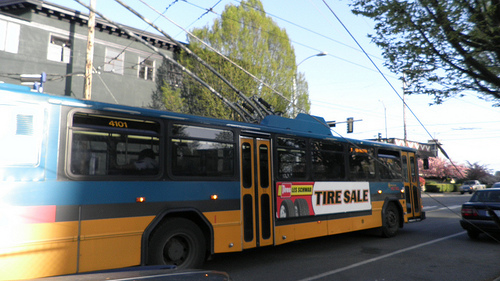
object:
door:
[240, 135, 276, 248]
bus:
[2, 83, 432, 270]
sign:
[273, 180, 368, 217]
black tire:
[153, 217, 210, 267]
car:
[455, 187, 500, 239]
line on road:
[411, 207, 463, 253]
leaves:
[383, 19, 442, 62]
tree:
[374, 0, 498, 106]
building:
[0, 5, 290, 113]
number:
[105, 120, 131, 128]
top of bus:
[1, 96, 421, 153]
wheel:
[378, 202, 401, 234]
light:
[208, 193, 214, 200]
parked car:
[454, 180, 483, 194]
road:
[236, 206, 499, 280]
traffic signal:
[324, 116, 355, 132]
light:
[312, 50, 327, 59]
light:
[373, 187, 386, 194]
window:
[72, 133, 157, 179]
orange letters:
[103, 118, 133, 128]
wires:
[47, 8, 375, 107]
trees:
[412, 156, 467, 184]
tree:
[165, 14, 305, 113]